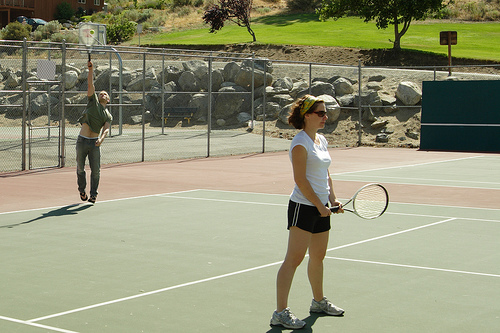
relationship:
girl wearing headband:
[273, 93, 343, 332] [299, 97, 318, 111]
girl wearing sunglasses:
[273, 93, 343, 332] [310, 109, 328, 117]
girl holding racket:
[273, 93, 343, 332] [336, 182, 390, 220]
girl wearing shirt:
[273, 93, 343, 332] [292, 133, 332, 204]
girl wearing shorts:
[273, 93, 343, 332] [288, 200, 331, 232]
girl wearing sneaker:
[273, 93, 343, 332] [270, 310, 306, 326]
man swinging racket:
[75, 25, 113, 203] [336, 182, 390, 220]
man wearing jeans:
[75, 25, 113, 203] [76, 135, 100, 201]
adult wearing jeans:
[75, 25, 113, 203] [76, 135, 100, 201]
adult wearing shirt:
[75, 25, 113, 203] [292, 133, 332, 204]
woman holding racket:
[273, 93, 343, 332] [336, 182, 390, 220]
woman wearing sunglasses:
[273, 93, 343, 332] [310, 109, 328, 117]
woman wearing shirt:
[273, 93, 343, 332] [292, 133, 332, 204]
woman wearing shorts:
[273, 93, 343, 332] [288, 200, 331, 232]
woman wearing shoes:
[273, 93, 343, 332] [269, 299, 345, 329]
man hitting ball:
[75, 25, 113, 203] [88, 27, 96, 38]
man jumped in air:
[75, 25, 113, 203] [77, 190, 101, 207]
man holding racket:
[75, 25, 113, 203] [78, 22, 97, 60]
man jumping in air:
[75, 25, 113, 203] [77, 190, 101, 207]